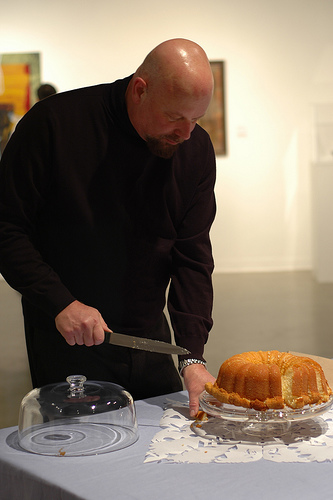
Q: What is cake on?
A: Dish.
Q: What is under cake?
A: Paper.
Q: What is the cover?
A: Glass.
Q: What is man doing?
A: Cutting cake.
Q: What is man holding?
A: Knife.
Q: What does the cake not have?
A: Frosting.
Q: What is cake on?
A: Platter.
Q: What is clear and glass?
A: The cake dome.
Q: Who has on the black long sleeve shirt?
A: The man.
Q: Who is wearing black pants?
A: The man.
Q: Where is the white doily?
A: Under the cake platter.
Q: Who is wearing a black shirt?
A: The man.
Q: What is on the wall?
A: Artwork.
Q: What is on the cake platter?
A: A sponge cake.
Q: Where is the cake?
A: On top on the table.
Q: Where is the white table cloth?
A: On the table.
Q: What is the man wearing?
A: Pants.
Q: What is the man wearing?
A: Shirt.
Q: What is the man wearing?
A: Pants.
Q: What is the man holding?
A: Knife.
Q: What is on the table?
A: Cake.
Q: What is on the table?
A: Cake.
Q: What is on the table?
A: Knife.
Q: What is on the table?
A: Cake.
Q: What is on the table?
A: Glass.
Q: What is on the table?
A: Cake.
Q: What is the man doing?
A: Cutting.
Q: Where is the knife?
A: In the man's hand.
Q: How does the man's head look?
A: He is bald.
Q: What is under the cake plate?
A: A paper doily.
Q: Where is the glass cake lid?
A: To the left.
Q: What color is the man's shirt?
A: Black.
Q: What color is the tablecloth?
A: Light blue.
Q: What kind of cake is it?
A: Yellow bundt.